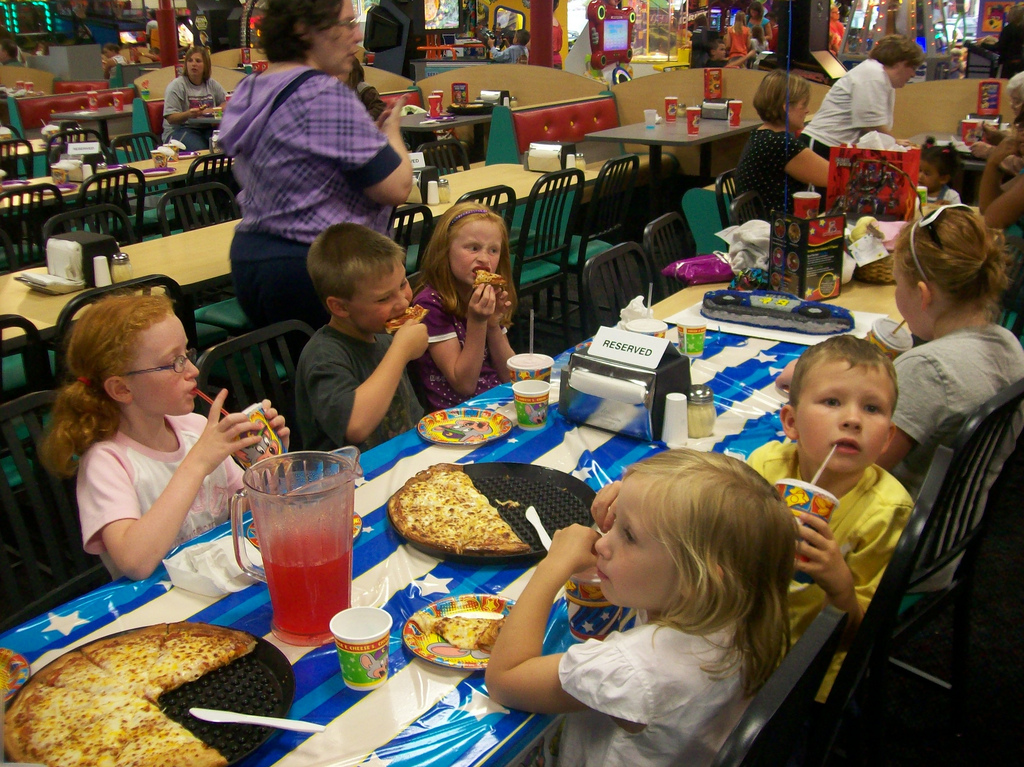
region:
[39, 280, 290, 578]
kids eating pizza at a party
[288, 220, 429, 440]
kids eating pizza at a party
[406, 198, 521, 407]
kids eating pizza at a party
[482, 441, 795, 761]
kids eating pizza at a party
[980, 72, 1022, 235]
kids eating pizza at a party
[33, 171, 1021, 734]
Children sitting at a table.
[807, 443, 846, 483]
A plastic straw.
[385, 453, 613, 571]
A black round pizza tray.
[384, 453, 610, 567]
Half of a pizza.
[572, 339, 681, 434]
A silver and black napkin holder.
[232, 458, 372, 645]
A pitcher of red drink.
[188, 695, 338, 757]
A white plastic knife.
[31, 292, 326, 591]
A girl wearing glasses.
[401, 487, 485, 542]
a cheese pizza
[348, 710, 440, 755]
a table cloth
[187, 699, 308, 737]
a white knife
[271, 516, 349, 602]
a pitcher of red juice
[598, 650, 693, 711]
girl is wearing a white shirt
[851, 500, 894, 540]
a yellow shirt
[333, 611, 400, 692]
a small cup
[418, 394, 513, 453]
a plate on the table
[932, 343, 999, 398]
a grey shirt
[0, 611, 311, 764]
slices of cheese pizza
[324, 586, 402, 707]
a cup on the table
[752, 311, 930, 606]
kid with a top yellow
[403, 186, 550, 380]
kid with blonde hair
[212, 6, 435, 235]
woman has purple jacket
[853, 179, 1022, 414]
the kid is blonde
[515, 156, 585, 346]
chair with green cushion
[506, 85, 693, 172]
bench is color red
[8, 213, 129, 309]
a box of napkin on a table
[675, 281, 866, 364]
A birthday cake.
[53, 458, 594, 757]
Pizza on the table.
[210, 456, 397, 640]
A pitcher of drink.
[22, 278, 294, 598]
A small girl drinking.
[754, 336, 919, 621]
A small boy drinking.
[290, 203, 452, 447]
A boy eating pizza.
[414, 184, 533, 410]
A girl eating pizza.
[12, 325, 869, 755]
A blue and white tablecloth.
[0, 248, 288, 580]
A girl with orange hair.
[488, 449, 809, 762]
A girl with blonde hair.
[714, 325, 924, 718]
boy with a yellow shirt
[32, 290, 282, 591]
girl with a pink shirt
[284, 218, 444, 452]
boy with a grey shirt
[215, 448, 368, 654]
pitcher of a red drink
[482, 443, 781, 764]
girl with a white shirt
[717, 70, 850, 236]
woman with a black shirt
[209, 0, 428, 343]
woman with a purple shirt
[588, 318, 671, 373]
sign on the napkin holder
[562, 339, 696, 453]
napkin holder on the kid's table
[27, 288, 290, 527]
a person is sitting down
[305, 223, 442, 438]
a person is sitting down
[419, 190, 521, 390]
a person is sitting down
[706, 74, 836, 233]
a person is sitting down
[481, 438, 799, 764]
a person is sitting down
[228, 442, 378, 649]
a pitcher with pink liquid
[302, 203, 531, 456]
two kids eating pizza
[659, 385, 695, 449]
a white salt shaker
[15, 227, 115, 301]
an open napkin holder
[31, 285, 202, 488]
a young girl with red hair